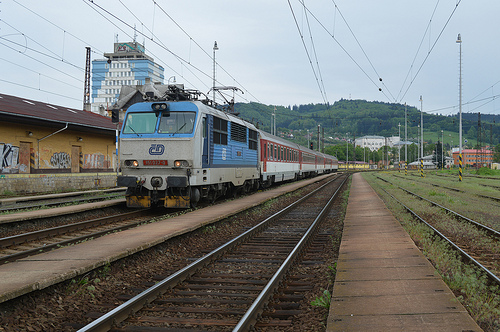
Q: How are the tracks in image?
A: Metal.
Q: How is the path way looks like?
A: Light brown.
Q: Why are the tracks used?
A: Trains.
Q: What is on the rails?
A: A train.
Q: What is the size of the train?
A: Long.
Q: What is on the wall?
A: Graffiti.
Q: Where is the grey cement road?
A: Between the trucks.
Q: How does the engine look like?
A: White and blue.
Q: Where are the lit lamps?
A: On the engine.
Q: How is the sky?
A: Overcast.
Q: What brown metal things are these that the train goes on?
A: Tracks.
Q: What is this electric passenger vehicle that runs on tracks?
A: Train.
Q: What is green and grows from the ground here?
A: Grass.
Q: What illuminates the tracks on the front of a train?
A: Headlights.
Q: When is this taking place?
A: Daytime.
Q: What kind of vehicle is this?
A: Train.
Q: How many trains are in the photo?
A: One.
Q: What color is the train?
A: Blue , red , silver.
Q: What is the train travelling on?
A: Train tracks.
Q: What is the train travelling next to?
A: Platform.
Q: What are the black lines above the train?
A: Power lines.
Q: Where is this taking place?
A: On the train tracks.